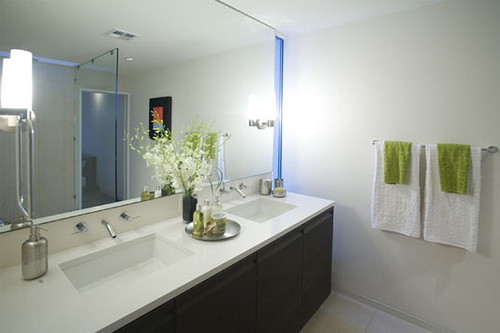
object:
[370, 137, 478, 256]
towels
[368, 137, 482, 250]
washcloths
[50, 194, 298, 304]
sinks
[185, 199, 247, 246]
tray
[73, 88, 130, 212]
door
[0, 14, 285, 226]
mirror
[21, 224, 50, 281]
soap dispenser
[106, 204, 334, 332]
cabinets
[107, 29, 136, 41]
ceiling vent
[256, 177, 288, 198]
containers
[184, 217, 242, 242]
plate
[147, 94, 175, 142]
frame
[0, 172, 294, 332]
countertop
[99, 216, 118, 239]
faucets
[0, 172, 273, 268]
wall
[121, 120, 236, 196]
bouquet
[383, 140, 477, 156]
rack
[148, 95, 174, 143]
artwork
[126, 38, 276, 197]
wall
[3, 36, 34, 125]
light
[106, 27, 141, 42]
vent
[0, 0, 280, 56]
ceiling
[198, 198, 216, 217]
lotion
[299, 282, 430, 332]
floor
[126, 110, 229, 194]
flowers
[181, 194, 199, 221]
vase